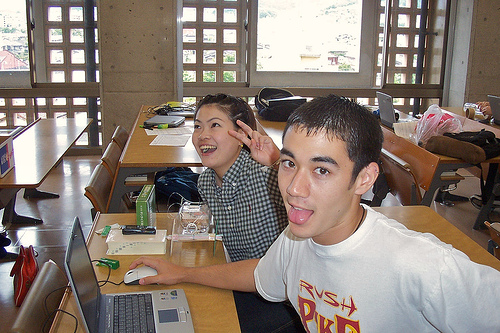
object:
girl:
[191, 91, 279, 331]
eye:
[194, 124, 202, 130]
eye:
[209, 122, 222, 129]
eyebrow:
[192, 118, 202, 124]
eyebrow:
[206, 117, 225, 123]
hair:
[194, 92, 258, 131]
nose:
[197, 127, 211, 141]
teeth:
[203, 145, 205, 148]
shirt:
[198, 144, 281, 263]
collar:
[207, 169, 241, 191]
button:
[227, 205, 232, 210]